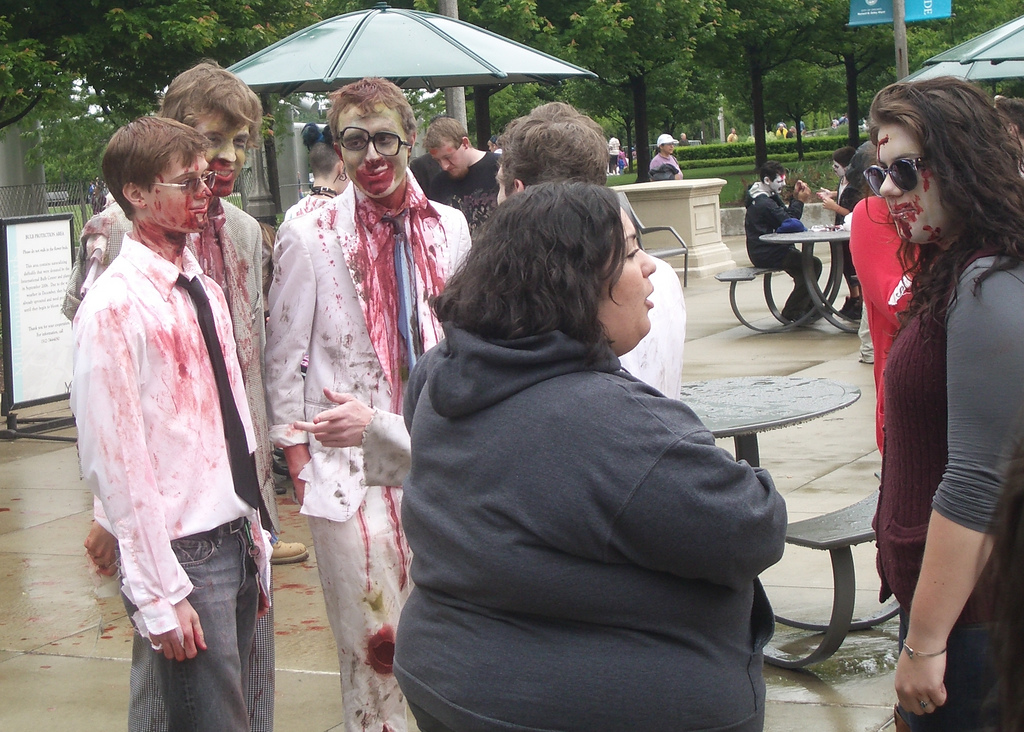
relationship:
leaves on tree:
[603, 20, 693, 153] [603, 20, 693, 153]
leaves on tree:
[691, 27, 769, 170] [691, 27, 769, 170]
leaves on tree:
[590, 8, 677, 198] [590, 8, 677, 198]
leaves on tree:
[150, 3, 239, 76] [150, 3, 239, 76]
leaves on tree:
[590, 8, 774, 158] [590, 8, 774, 158]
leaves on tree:
[539, 25, 644, 123] [539, 25, 644, 123]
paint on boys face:
[289, 97, 479, 266] [289, 97, 479, 266]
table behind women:
[713, 387, 935, 650] [409, 179, 935, 650]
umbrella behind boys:
[262, 27, 507, 94] [31, 27, 507, 585]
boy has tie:
[72, 139, 289, 726] [107, 273, 221, 507]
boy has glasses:
[262, 83, 404, 670] [303, 85, 417, 196]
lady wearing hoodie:
[417, 203, 709, 653] [417, 203, 709, 653]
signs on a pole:
[845, 6, 964, 46] [845, 47, 964, 99]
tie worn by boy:
[151, 258, 276, 486] [63, 126, 276, 485]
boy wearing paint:
[292, 83, 420, 220] [288, 97, 479, 266]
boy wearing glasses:
[292, 83, 420, 220] [292, 83, 420, 220]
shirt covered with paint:
[72, 138, 294, 632] [288, 97, 479, 266]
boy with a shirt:
[72, 138, 294, 632] [72, 138, 294, 632]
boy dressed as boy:
[72, 139, 289, 726] [72, 139, 289, 726]